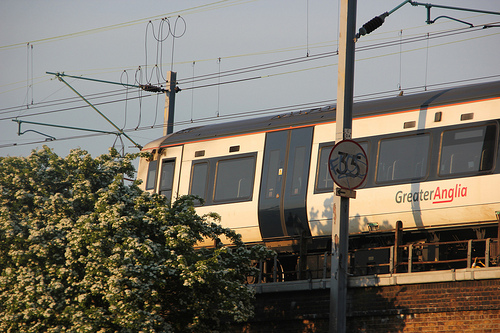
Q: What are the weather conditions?
A: It is clear.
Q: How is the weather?
A: It is clear.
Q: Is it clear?
A: Yes, it is clear.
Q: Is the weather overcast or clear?
A: It is clear.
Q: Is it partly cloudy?
A: No, it is clear.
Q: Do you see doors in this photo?
A: Yes, there is a door.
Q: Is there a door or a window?
A: Yes, there is a door.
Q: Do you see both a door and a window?
A: Yes, there are both a door and a window.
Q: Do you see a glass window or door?
A: Yes, there is a glass door.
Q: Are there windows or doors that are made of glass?
A: Yes, the door is made of glass.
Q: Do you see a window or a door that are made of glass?
A: Yes, the door is made of glass.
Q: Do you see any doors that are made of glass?
A: Yes, there is a door that is made of glass.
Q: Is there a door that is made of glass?
A: Yes, there is a door that is made of glass.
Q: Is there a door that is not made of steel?
A: Yes, there is a door that is made of glass.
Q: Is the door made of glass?
A: Yes, the door is made of glass.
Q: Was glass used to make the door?
A: Yes, the door is made of glass.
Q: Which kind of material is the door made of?
A: The door is made of glass.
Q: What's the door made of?
A: The door is made of glass.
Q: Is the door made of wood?
A: No, the door is made of glass.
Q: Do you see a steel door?
A: No, there is a door but it is made of glass.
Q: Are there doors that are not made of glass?
A: No, there is a door but it is made of glass.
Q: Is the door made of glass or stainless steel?
A: The door is made of glass.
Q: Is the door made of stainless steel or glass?
A: The door is made of glass.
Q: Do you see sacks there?
A: No, there are no sacks.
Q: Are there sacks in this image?
A: No, there are no sacks.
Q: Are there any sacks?
A: No, there are no sacks.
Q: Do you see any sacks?
A: No, there are no sacks.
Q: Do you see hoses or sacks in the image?
A: No, there are no sacks or hoses.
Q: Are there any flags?
A: No, there are no flags.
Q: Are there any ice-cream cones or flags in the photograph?
A: No, there are no flags or ice-cream cones.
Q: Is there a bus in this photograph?
A: No, there are no buses.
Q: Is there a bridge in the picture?
A: Yes, there is a bridge.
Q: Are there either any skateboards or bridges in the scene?
A: Yes, there is a bridge.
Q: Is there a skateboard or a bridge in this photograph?
A: Yes, there is a bridge.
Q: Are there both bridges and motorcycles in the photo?
A: No, there is a bridge but no motorcycles.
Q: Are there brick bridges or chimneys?
A: Yes, there is a brick bridge.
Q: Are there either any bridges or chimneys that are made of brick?
A: Yes, the bridge is made of brick.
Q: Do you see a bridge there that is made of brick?
A: Yes, there is a bridge that is made of brick.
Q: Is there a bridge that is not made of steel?
A: Yes, there is a bridge that is made of brick.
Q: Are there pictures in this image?
A: No, there are no pictures.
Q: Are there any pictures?
A: No, there are no pictures.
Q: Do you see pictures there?
A: No, there are no pictures.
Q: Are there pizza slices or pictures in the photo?
A: No, there are no pictures or pizza slices.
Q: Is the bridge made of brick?
A: Yes, the bridge is made of brick.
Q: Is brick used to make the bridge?
A: Yes, the bridge is made of brick.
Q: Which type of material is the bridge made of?
A: The bridge is made of brick.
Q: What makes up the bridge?
A: The bridge is made of brick.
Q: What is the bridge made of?
A: The bridge is made of brick.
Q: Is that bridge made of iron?
A: No, the bridge is made of brick.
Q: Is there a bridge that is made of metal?
A: No, there is a bridge but it is made of brick.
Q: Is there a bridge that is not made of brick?
A: No, there is a bridge but it is made of brick.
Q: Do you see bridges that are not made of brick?
A: No, there is a bridge but it is made of brick.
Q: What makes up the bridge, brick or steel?
A: The bridge is made of brick.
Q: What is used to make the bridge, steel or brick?
A: The bridge is made of brick.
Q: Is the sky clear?
A: Yes, the sky is clear.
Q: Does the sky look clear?
A: Yes, the sky is clear.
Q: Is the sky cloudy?
A: No, the sky is clear.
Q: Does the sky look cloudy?
A: No, the sky is clear.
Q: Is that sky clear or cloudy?
A: The sky is clear.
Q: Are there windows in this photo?
A: Yes, there is a window.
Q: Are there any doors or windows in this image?
A: Yes, there is a window.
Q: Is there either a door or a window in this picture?
A: Yes, there is a window.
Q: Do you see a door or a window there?
A: Yes, there is a window.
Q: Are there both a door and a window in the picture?
A: Yes, there are both a window and a door.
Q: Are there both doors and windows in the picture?
A: Yes, there are both a window and doors.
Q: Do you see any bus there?
A: No, there are no buses.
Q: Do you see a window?
A: Yes, there is a window.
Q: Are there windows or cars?
A: Yes, there is a window.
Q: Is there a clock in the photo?
A: No, there are no clocks.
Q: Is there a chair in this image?
A: No, there are no chairs.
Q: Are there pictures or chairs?
A: No, there are no chairs or pictures.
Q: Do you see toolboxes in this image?
A: No, there are no toolboxes.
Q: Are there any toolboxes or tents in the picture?
A: No, there are no toolboxes or tents.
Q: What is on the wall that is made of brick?
A: The shrub is on the wall.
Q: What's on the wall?
A: The shrub is on the wall.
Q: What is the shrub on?
A: The shrub is on the wall.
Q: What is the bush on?
A: The shrub is on the wall.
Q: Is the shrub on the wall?
A: Yes, the shrub is on the wall.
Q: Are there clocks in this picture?
A: No, there are no clocks.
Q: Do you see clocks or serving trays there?
A: No, there are no clocks or serving trays.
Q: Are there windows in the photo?
A: Yes, there is a window.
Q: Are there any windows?
A: Yes, there is a window.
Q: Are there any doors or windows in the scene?
A: Yes, there is a window.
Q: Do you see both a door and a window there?
A: Yes, there are both a window and a door.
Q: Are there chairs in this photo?
A: No, there are no chairs.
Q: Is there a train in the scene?
A: Yes, there is a train.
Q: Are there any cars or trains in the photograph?
A: Yes, there is a train.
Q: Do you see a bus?
A: No, there are no buses.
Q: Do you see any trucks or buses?
A: No, there are no buses or trucks.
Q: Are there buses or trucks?
A: No, there are no buses or trucks.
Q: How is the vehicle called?
A: The vehicle is a train.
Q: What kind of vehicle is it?
A: The vehicle is a train.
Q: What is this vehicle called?
A: That is a train.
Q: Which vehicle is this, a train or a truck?
A: That is a train.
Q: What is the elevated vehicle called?
A: The vehicle is a train.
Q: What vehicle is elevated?
A: The vehicle is a train.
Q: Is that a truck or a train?
A: That is a train.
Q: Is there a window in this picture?
A: Yes, there is a window.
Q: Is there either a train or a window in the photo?
A: Yes, there is a window.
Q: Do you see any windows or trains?
A: Yes, there is a window.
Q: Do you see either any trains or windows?
A: Yes, there is a window.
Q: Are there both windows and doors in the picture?
A: Yes, there are both a window and a door.